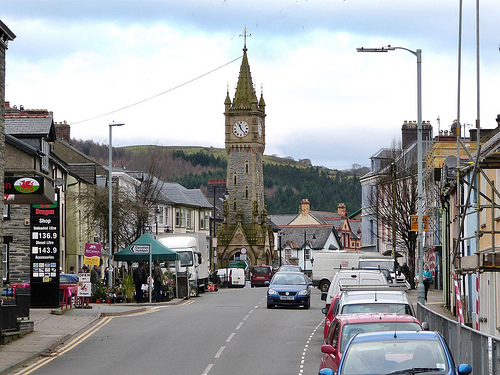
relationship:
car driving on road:
[264, 269, 314, 310] [0, 283, 329, 373]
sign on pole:
[408, 209, 429, 232] [416, 47, 421, 294]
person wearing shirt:
[130, 254, 144, 304] [421, 265, 433, 279]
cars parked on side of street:
[322, 262, 469, 374] [16, 276, 331, 373]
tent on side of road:
[124, 226, 198, 296] [0, 283, 329, 373]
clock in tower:
[231, 117, 249, 136] [204, 29, 305, 273]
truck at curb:
[150, 225, 205, 297] [122, 295, 184, 304]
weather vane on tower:
[238, 16, 263, 54] [223, 49, 267, 278]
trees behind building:
[264, 144, 374, 224] [224, 29, 263, 283]